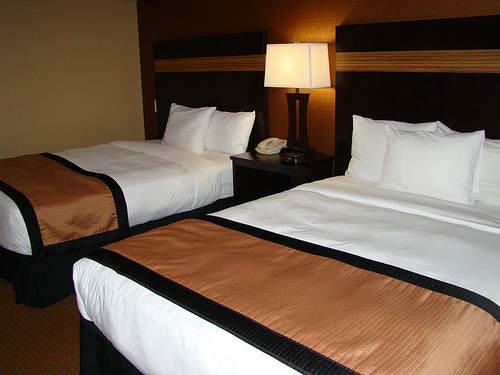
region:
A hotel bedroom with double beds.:
[2, 5, 496, 372]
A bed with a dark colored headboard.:
[77, 23, 497, 373]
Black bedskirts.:
[3, 250, 142, 371]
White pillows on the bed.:
[162, 100, 254, 155]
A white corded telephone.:
[251, 132, 287, 155]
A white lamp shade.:
[258, 40, 333, 90]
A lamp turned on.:
[260, 31, 330, 165]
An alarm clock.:
[282, 148, 304, 165]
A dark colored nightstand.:
[228, 139, 335, 214]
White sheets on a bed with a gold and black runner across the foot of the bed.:
[80, 167, 499, 369]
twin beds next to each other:
[18, 33, 496, 363]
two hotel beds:
[15, 22, 462, 374]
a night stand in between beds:
[203, 114, 331, 215]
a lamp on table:
[235, 35, 343, 175]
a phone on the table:
[233, 26, 335, 190]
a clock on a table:
[239, 121, 323, 195]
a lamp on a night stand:
[247, 19, 349, 204]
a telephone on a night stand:
[242, 122, 322, 194]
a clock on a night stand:
[233, 126, 315, 175]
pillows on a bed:
[122, 74, 247, 181]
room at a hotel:
[1, 2, 499, 370]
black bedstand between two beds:
[223, 130, 337, 216]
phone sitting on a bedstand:
[251, 136, 288, 158]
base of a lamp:
[278, 90, 317, 152]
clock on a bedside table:
[278, 147, 307, 165]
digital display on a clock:
[281, 153, 295, 163]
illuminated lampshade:
[261, 37, 332, 93]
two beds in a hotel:
[1, 127, 499, 373]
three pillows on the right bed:
[340, 113, 497, 221]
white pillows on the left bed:
[158, 92, 260, 166]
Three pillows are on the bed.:
[343, 107, 498, 219]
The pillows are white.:
[338, 110, 495, 219]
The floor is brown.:
[16, 324, 68, 373]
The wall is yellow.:
[24, 35, 105, 115]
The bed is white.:
[363, 225, 443, 252]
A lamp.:
[248, 25, 348, 182]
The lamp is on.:
[239, 25, 336, 175]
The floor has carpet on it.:
[5, 317, 66, 374]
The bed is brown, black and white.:
[241, 208, 413, 310]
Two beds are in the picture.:
[3, 37, 498, 374]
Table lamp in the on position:
[251, 38, 341, 166]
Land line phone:
[249, 132, 277, 154]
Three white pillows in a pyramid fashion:
[341, 110, 498, 206]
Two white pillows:
[161, 93, 252, 168]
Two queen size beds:
[3, 90, 498, 370]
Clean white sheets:
[228, 212, 491, 264]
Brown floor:
[5, 312, 77, 372]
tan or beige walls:
[10, 80, 136, 138]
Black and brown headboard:
[336, 11, 493, 126]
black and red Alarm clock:
[283, 147, 308, 164]